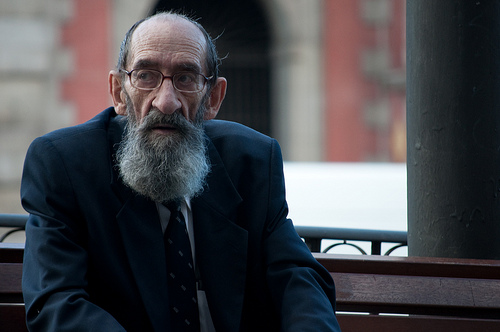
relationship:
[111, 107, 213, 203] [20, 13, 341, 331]
moustache worn on man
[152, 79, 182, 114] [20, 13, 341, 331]
nose on man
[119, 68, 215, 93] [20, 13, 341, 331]
eyeglasses being worn by man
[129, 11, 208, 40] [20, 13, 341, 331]
hair line of man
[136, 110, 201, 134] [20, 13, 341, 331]
moustache worn on man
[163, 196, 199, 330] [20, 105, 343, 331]
necktie worn with suit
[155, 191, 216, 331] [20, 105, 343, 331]
shirt worn with suit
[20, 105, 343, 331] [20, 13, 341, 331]
suit worn by man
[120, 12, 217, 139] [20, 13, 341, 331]
head of man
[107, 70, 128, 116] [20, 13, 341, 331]
ear of man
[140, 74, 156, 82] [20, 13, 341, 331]
eye of man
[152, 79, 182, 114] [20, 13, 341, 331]
nose of man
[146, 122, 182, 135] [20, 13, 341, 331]
mouth of man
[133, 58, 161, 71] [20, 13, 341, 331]
eyebrow of man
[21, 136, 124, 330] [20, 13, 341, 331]
arm of man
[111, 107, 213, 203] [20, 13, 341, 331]
moustache of man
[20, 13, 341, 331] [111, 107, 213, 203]
man with moustache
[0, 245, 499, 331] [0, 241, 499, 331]
bench of bench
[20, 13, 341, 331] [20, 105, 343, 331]
man wearing suit